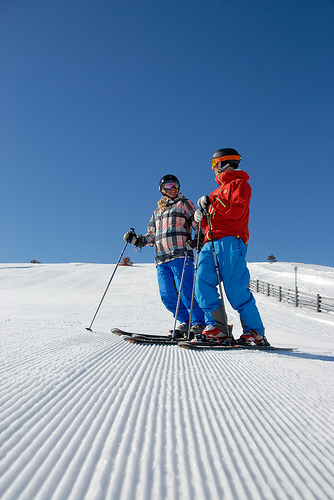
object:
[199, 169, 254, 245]
jacket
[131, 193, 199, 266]
jacket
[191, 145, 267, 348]
person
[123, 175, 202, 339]
person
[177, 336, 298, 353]
skis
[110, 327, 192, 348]
skis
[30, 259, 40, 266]
building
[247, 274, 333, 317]
fence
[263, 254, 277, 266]
tree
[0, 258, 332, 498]
snow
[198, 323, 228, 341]
boot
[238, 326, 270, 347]
boot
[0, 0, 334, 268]
sky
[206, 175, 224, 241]
zipper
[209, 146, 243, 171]
helmet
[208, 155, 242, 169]
goggles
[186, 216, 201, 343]
ski pole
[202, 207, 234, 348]
ski pole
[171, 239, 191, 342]
ski pole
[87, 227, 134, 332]
ski pole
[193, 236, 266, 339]
ski pants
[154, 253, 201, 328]
ski pants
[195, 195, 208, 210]
glove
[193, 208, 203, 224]
glove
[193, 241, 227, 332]
leg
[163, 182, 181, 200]
face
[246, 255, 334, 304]
hill